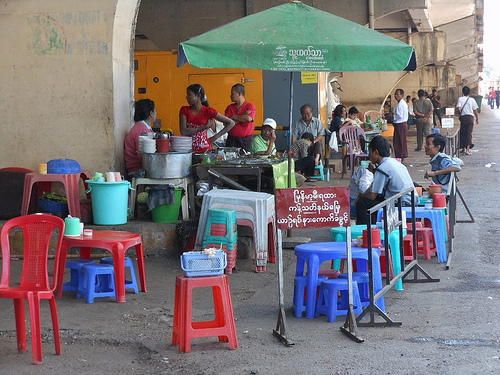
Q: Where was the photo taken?
A: It was taken at the sidewalk.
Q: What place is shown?
A: It is a sidewalk.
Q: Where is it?
A: This is at the sidewalk.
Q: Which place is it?
A: It is a sidewalk.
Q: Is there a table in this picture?
A: Yes, there is a table.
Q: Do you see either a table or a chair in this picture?
A: Yes, there is a table.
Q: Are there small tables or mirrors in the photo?
A: Yes, there is a small table.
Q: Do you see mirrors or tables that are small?
A: Yes, the table is small.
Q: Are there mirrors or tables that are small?
A: Yes, the table is small.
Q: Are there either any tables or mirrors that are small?
A: Yes, the table is small.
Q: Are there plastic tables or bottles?
A: Yes, there is a plastic table.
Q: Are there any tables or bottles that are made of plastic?
A: Yes, the table is made of plastic.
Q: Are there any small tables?
A: Yes, there is a small table.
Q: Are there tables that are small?
A: Yes, there is a table that is small.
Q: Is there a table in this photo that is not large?
A: Yes, there is a small table.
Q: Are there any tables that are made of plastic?
A: Yes, there is a table that is made of plastic.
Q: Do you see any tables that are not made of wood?
A: Yes, there is a table that is made of plastic.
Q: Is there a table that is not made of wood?
A: Yes, there is a table that is made of plastic.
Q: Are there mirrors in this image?
A: No, there are no mirrors.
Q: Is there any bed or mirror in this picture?
A: No, there are no mirrors or beds.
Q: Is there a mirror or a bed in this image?
A: No, there are no mirrors or beds.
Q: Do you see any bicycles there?
A: No, there are no bicycles.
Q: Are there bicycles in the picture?
A: No, there are no bicycles.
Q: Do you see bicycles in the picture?
A: No, there are no bicycles.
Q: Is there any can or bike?
A: No, there are no bikes or cans.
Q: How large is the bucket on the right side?
A: The bucket is small.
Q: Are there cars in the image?
A: No, there are no cars.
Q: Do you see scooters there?
A: No, there are no scooters.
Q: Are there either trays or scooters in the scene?
A: No, there are no scooters or trays.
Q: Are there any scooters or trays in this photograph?
A: No, there are no scooters or trays.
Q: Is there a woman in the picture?
A: Yes, there is a woman.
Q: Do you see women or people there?
A: Yes, there is a woman.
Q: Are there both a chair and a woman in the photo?
A: Yes, there are both a woman and a chair.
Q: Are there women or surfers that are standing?
A: Yes, the woman is standing.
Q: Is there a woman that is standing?
A: Yes, there is a woman that is standing.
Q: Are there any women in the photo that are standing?
A: Yes, there is a woman that is standing.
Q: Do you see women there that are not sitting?
A: Yes, there is a woman that is standing .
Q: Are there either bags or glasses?
A: No, there are no glasses or bags.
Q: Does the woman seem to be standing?
A: Yes, the woman is standing.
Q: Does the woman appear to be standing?
A: Yes, the woman is standing.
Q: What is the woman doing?
A: The woman is standing.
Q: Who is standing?
A: The woman is standing.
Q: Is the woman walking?
A: No, the woman is standing.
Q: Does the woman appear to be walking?
A: No, the woman is standing.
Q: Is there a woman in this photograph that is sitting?
A: No, there is a woman but she is standing.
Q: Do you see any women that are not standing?
A: No, there is a woman but she is standing.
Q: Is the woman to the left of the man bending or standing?
A: The woman is standing.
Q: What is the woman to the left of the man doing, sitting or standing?
A: The woman is standing.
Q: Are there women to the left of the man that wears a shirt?
A: Yes, there is a woman to the left of the man.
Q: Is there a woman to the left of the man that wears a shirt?
A: Yes, there is a woman to the left of the man.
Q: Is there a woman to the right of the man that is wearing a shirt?
A: No, the woman is to the left of the man.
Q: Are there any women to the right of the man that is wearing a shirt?
A: No, the woman is to the left of the man.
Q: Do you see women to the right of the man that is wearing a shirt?
A: No, the woman is to the left of the man.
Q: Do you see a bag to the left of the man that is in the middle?
A: No, there is a woman to the left of the man.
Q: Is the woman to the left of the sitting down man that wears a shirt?
A: Yes, the woman is to the left of the man.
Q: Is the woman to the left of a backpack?
A: No, the woman is to the left of the man.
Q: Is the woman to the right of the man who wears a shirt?
A: No, the woman is to the left of the man.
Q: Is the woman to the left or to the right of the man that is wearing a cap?
A: The woman is to the left of the man.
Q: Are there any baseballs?
A: No, there are no baseballs.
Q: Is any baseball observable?
A: No, there are no baseballs.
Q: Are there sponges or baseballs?
A: No, there are no baseballs or sponges.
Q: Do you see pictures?
A: No, there are no pictures.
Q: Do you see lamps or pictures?
A: No, there are no pictures or lamps.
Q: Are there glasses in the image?
A: No, there are no glasses.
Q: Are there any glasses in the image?
A: No, there are no glasses.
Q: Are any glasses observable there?
A: No, there are no glasses.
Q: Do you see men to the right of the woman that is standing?
A: Yes, there is a man to the right of the woman.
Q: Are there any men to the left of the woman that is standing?
A: No, the man is to the right of the woman.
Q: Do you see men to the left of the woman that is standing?
A: No, the man is to the right of the woman.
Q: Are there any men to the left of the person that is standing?
A: No, the man is to the right of the woman.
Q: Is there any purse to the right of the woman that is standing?
A: No, there is a man to the right of the woman.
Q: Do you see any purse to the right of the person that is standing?
A: No, there is a man to the right of the woman.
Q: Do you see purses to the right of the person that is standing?
A: No, there is a man to the right of the woman.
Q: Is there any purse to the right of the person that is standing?
A: No, there is a man to the right of the woman.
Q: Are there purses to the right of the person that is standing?
A: No, there is a man to the right of the woman.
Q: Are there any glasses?
A: No, there are no glasses.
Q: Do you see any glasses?
A: No, there are no glasses.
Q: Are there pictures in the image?
A: No, there are no pictures.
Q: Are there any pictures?
A: No, there are no pictures.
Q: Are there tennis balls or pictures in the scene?
A: No, there are no pictures or tennis balls.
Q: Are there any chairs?
A: Yes, there is a chair.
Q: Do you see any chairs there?
A: Yes, there is a chair.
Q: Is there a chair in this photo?
A: Yes, there is a chair.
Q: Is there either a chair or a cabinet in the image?
A: Yes, there is a chair.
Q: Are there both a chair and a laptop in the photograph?
A: No, there is a chair but no laptops.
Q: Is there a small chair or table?
A: Yes, there is a small chair.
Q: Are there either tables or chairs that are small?
A: Yes, the chair is small.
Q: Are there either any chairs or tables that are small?
A: Yes, the chair is small.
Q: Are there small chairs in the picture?
A: Yes, there is a small chair.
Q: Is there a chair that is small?
A: Yes, there is a chair that is small.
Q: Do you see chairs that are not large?
A: Yes, there is a small chair.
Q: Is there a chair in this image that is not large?
A: Yes, there is a small chair.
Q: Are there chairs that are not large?
A: Yes, there is a small chair.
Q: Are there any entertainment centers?
A: No, there are no entertainment centers.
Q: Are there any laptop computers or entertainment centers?
A: No, there are no entertainment centers or laptop computers.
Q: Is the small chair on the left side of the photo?
A: Yes, the chair is on the left of the image.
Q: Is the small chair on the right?
A: No, the chair is on the left of the image.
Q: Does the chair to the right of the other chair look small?
A: Yes, the chair is small.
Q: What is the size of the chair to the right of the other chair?
A: The chair is small.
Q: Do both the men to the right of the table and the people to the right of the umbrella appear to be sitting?
A: Yes, both the men and the people are sitting.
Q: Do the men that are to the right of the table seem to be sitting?
A: Yes, the men are sitting.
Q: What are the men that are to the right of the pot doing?
A: The men are sitting.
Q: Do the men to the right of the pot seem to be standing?
A: No, the men are sitting.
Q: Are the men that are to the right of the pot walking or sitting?
A: The men are sitting.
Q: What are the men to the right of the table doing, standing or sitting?
A: The men are sitting.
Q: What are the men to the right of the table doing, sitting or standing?
A: The men are sitting.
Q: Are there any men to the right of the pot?
A: Yes, there are men to the right of the pot.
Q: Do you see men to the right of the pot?
A: Yes, there are men to the right of the pot.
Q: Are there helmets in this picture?
A: No, there are no helmets.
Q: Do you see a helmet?
A: No, there are no helmets.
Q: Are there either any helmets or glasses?
A: No, there are no helmets or glasses.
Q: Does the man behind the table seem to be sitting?
A: Yes, the man is sitting.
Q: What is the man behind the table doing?
A: The man is sitting.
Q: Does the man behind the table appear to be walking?
A: No, the man is sitting.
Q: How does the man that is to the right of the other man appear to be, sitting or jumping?
A: The man is sitting.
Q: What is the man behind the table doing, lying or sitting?
A: The man is sitting.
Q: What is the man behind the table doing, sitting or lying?
A: The man is sitting.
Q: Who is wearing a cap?
A: The man is wearing a cap.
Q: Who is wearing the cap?
A: The man is wearing a cap.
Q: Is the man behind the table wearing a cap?
A: Yes, the man is wearing a cap.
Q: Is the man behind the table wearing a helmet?
A: No, the man is wearing a cap.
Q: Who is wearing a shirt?
A: The man is wearing a shirt.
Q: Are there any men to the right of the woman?
A: Yes, there is a man to the right of the woman.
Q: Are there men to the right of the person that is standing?
A: Yes, there is a man to the right of the woman.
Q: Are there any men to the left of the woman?
A: No, the man is to the right of the woman.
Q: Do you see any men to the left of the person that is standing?
A: No, the man is to the right of the woman.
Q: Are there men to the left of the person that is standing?
A: No, the man is to the right of the woman.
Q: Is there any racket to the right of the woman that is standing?
A: No, there is a man to the right of the woman.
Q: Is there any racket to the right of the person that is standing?
A: No, there is a man to the right of the woman.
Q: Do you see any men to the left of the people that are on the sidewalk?
A: Yes, there is a man to the left of the people.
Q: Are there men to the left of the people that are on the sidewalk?
A: Yes, there is a man to the left of the people.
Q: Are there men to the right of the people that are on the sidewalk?
A: No, the man is to the left of the people.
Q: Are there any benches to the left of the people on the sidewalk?
A: No, there is a man to the left of the people.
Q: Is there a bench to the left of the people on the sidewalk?
A: No, there is a man to the left of the people.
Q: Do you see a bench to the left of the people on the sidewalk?
A: No, there is a man to the left of the people.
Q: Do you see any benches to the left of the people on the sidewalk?
A: No, there is a man to the left of the people.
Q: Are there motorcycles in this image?
A: No, there are no motorcycles.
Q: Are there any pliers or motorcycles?
A: No, there are no motorcycles or pliers.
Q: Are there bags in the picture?
A: No, there are no bags.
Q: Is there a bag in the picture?
A: No, there are no bags.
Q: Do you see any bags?
A: No, there are no bags.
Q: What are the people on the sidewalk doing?
A: The people are walking.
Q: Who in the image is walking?
A: The people are walking.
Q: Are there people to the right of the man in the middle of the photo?
A: Yes, there are people to the right of the man.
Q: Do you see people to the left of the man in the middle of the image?
A: No, the people are to the right of the man.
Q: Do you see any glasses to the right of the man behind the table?
A: No, there are people to the right of the man.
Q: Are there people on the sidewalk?
A: Yes, there are people on the sidewalk.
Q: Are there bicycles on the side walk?
A: No, there are people on the side walk.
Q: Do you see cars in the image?
A: No, there are no cars.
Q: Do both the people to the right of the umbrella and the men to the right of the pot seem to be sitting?
A: Yes, both the people and the men are sitting.